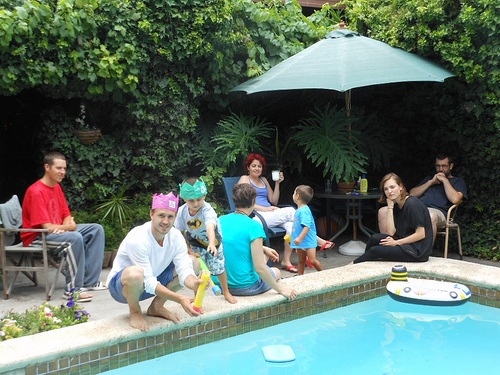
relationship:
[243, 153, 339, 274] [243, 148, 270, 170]
woman has red hair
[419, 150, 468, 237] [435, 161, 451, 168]
man wearing glasses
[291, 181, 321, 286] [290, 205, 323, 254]
toddler wearing shirt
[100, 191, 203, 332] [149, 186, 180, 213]
man wearing crown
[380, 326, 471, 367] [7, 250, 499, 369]
water in swimming pool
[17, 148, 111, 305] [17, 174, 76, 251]
man wearing red shirt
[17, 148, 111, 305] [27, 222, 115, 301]
man wearing pants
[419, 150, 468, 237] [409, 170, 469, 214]
man wearing black shirt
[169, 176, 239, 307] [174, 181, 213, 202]
boy wearing crown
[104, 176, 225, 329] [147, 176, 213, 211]
two people are wearing crowns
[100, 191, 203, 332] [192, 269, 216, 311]
man holds toy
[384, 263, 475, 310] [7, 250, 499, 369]
floaty in swimming pool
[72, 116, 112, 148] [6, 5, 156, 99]
basket hanging from tree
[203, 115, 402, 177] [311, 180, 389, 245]
palms hang over table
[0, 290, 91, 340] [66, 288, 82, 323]
garden has flowers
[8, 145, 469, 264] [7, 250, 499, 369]
people are sitting by swimming pool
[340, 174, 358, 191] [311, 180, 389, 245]
pot on table